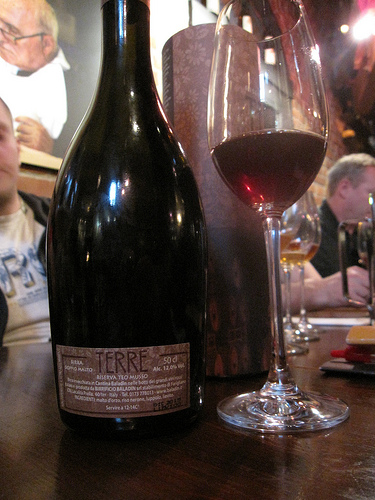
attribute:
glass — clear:
[204, 2, 352, 432]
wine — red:
[213, 130, 325, 215]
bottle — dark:
[37, 0, 215, 428]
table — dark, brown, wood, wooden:
[3, 302, 358, 498]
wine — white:
[284, 250, 304, 264]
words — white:
[64, 370, 190, 410]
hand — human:
[314, 262, 363, 307]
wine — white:
[283, 233, 298, 266]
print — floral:
[172, 29, 214, 127]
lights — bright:
[352, 13, 374, 39]